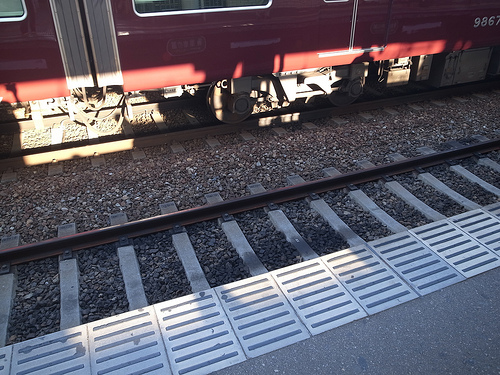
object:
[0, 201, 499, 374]
rectangles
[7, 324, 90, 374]
tile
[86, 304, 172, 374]
tile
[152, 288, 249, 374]
tile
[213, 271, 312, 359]
tile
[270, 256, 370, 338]
tile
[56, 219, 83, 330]
tie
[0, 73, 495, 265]
rail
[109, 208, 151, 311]
tie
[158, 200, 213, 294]
tie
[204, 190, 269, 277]
tie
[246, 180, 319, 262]
tie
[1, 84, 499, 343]
gravel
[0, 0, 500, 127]
train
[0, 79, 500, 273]
tracks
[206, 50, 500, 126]
machinery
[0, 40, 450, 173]
sunlight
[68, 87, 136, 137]
cables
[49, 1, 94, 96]
panel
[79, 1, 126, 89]
panel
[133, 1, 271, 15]
window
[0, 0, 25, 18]
window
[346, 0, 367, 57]
line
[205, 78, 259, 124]
wheel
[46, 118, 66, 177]
tie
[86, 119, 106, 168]
tie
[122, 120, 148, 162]
tie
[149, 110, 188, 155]
tie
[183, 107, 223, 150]
tie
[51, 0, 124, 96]
connector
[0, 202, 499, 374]
platform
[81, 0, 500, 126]
train car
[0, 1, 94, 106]
train car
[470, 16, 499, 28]
numbers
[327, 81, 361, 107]
wheel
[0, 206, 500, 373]
pavement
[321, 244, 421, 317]
tile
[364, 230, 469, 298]
tile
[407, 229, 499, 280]
tile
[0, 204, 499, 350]
line